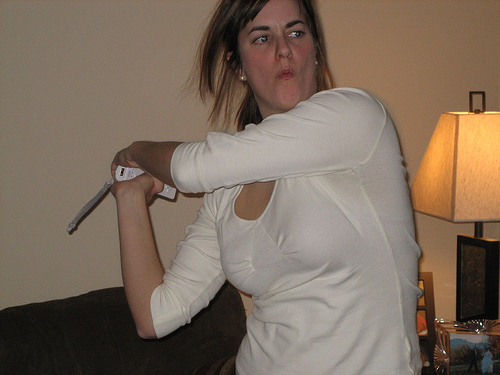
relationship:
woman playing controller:
[108, 10, 426, 371] [113, 163, 176, 199]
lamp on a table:
[410, 80, 480, 322] [428, 325, 485, 362]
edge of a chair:
[417, 268, 436, 367] [419, 268, 435, 368]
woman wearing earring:
[108, 10, 426, 371] [313, 60, 319, 65]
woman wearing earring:
[108, 10, 426, 371] [239, 74, 246, 81]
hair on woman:
[175, 0, 338, 130] [108, 10, 426, 371]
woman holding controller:
[108, 10, 426, 371] [113, 163, 176, 199]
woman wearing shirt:
[108, 10, 426, 371] [148, 83, 418, 369]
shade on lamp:
[409, 107, 499, 223] [410, 90, 494, 321]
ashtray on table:
[437, 313, 493, 335] [426, 324, 498, 373]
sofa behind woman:
[0, 279, 252, 371] [108, 10, 426, 371]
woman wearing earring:
[108, 10, 426, 371] [235, 70, 248, 81]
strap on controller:
[63, 182, 114, 234] [113, 163, 178, 199]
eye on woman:
[286, 25, 307, 41] [108, 10, 426, 371]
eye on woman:
[251, 33, 271, 45] [108, 10, 426, 371]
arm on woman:
[110, 81, 390, 193] [108, 10, 426, 371]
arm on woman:
[113, 170, 223, 343] [108, 10, 426, 371]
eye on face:
[251, 33, 271, 45] [235, 0, 316, 111]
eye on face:
[286, 28, 307, 41] [235, 0, 316, 111]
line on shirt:
[353, 169, 415, 373] [148, 83, 418, 369]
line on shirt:
[347, 85, 387, 174] [148, 83, 418, 369]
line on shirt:
[353, 161, 415, 372] [148, 83, 418, 369]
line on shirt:
[360, 103, 386, 174] [148, 83, 418, 369]